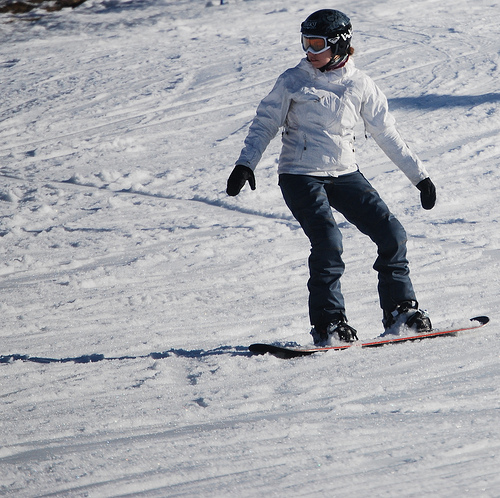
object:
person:
[225, 8, 437, 346]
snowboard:
[246, 315, 491, 358]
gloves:
[226, 164, 257, 195]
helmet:
[297, 7, 353, 57]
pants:
[277, 165, 419, 327]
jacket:
[234, 55, 428, 187]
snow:
[0, 0, 499, 497]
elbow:
[241, 117, 277, 147]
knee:
[305, 232, 348, 265]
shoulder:
[272, 64, 304, 100]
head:
[297, 8, 354, 71]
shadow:
[0, 338, 301, 367]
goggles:
[299, 30, 326, 55]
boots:
[307, 321, 359, 349]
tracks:
[0, 63, 288, 155]